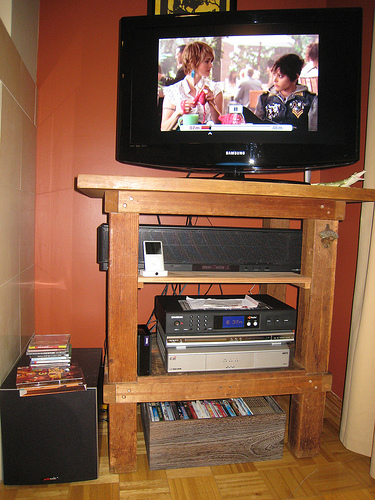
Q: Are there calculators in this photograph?
A: No, there are no calculators.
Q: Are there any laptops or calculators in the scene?
A: No, there are no calculators or laptops.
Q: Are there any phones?
A: Yes, there is a phone.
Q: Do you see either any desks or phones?
A: Yes, there is a phone.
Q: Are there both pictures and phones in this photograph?
A: Yes, there are both a phone and a picture.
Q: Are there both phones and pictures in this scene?
A: Yes, there are both a phone and a picture.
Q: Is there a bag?
A: No, there are no bags.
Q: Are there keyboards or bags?
A: No, there are no bags or keyboards.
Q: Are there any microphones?
A: No, there are no microphones.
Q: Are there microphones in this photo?
A: No, there are no microphones.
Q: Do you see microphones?
A: No, there are no microphones.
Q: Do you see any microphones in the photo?
A: No, there are no microphones.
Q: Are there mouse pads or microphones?
A: No, there are no microphones or mouse pads.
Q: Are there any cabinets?
A: No, there are no cabinets.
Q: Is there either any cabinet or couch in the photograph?
A: No, there are no cabinets or couches.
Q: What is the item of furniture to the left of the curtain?
A: The piece of furniture is a shelf.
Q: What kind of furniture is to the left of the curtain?
A: The piece of furniture is a shelf.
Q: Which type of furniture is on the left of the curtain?
A: The piece of furniture is a shelf.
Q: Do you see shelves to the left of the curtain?
A: Yes, there is a shelf to the left of the curtain.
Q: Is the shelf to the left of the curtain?
A: Yes, the shelf is to the left of the curtain.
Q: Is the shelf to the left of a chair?
A: No, the shelf is to the left of the curtain.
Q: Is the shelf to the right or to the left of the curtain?
A: The shelf is to the left of the curtain.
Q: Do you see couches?
A: No, there are no couches.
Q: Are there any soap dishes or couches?
A: No, there are no couches or soap dishes.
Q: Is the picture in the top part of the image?
A: Yes, the picture is in the top of the image.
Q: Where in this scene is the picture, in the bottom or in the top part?
A: The picture is in the top of the image.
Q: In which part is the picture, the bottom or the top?
A: The picture is in the top of the image.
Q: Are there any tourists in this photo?
A: No, there are no tourists.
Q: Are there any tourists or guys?
A: No, there are no tourists or guys.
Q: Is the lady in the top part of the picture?
A: Yes, the lady is in the top of the image.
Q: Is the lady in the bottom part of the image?
A: No, the lady is in the top of the image.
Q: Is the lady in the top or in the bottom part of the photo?
A: The lady is in the top of the image.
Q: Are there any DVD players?
A: Yes, there is a DVD player.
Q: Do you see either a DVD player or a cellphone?
A: Yes, there is a DVD player.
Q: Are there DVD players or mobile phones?
A: Yes, there is a DVD player.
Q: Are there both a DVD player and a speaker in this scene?
A: Yes, there are both a DVD player and a speaker.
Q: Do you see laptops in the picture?
A: No, there are no laptops.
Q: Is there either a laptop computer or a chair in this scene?
A: No, there are no laptops or chairs.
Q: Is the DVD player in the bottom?
A: Yes, the DVD player is in the bottom of the image.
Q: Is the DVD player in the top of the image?
A: No, the DVD player is in the bottom of the image.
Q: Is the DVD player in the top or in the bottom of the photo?
A: The DVD player is in the bottom of the image.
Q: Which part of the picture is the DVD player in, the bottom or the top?
A: The DVD player is in the bottom of the image.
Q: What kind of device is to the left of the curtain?
A: The device is a DVD player.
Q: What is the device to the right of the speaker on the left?
A: The device is a DVD player.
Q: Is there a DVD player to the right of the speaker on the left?
A: Yes, there is a DVD player to the right of the speaker.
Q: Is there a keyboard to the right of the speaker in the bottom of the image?
A: No, there is a DVD player to the right of the speaker.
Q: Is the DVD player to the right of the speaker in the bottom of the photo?
A: Yes, the DVD player is to the right of the speaker.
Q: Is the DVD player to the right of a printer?
A: No, the DVD player is to the right of the speaker.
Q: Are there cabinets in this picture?
A: No, there are no cabinets.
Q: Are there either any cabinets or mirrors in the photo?
A: No, there are no cabinets or mirrors.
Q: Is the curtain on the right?
A: Yes, the curtain is on the right of the image.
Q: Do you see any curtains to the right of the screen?
A: Yes, there is a curtain to the right of the screen.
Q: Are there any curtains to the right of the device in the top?
A: Yes, there is a curtain to the right of the screen.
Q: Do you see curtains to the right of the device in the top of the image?
A: Yes, there is a curtain to the right of the screen.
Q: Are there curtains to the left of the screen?
A: No, the curtain is to the right of the screen.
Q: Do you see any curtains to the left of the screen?
A: No, the curtain is to the right of the screen.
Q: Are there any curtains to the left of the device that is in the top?
A: No, the curtain is to the right of the screen.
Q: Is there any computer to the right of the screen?
A: No, there is a curtain to the right of the screen.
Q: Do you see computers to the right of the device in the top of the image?
A: No, there is a curtain to the right of the screen.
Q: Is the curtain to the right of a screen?
A: Yes, the curtain is to the right of a screen.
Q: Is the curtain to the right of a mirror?
A: No, the curtain is to the right of a screen.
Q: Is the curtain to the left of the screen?
A: No, the curtain is to the right of the screen.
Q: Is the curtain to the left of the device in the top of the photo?
A: No, the curtain is to the right of the screen.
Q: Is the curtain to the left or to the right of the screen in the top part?
A: The curtain is to the right of the screen.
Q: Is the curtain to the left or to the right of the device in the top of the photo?
A: The curtain is to the right of the screen.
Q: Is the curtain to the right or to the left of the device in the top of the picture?
A: The curtain is to the right of the screen.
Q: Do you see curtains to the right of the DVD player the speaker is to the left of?
A: Yes, there is a curtain to the right of the DVD player.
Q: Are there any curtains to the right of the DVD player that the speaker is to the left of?
A: Yes, there is a curtain to the right of the DVD player.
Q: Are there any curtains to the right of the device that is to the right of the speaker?
A: Yes, there is a curtain to the right of the DVD player.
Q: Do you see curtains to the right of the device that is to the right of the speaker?
A: Yes, there is a curtain to the right of the DVD player.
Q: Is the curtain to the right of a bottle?
A: No, the curtain is to the right of a DVD player.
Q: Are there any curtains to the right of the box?
A: Yes, there is a curtain to the right of the box.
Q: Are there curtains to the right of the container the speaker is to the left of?
A: Yes, there is a curtain to the right of the box.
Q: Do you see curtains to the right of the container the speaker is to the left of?
A: Yes, there is a curtain to the right of the box.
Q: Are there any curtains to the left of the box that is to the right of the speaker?
A: No, the curtain is to the right of the box.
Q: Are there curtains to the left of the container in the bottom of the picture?
A: No, the curtain is to the right of the box.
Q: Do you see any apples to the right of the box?
A: No, there is a curtain to the right of the box.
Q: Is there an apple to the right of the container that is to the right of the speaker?
A: No, there is a curtain to the right of the box.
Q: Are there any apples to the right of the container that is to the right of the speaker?
A: No, there is a curtain to the right of the box.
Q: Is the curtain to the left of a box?
A: No, the curtain is to the right of a box.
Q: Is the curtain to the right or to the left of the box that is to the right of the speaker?
A: The curtain is to the right of the box.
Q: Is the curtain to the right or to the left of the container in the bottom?
A: The curtain is to the right of the box.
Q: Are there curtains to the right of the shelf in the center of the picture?
A: Yes, there is a curtain to the right of the shelf.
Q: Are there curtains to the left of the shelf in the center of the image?
A: No, the curtain is to the right of the shelf.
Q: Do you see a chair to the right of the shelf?
A: No, there is a curtain to the right of the shelf.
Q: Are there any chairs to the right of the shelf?
A: No, there is a curtain to the right of the shelf.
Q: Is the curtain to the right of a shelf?
A: Yes, the curtain is to the right of a shelf.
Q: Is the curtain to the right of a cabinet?
A: No, the curtain is to the right of a shelf.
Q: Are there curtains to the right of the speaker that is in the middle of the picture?
A: Yes, there is a curtain to the right of the speaker.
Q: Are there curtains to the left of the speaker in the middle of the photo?
A: No, the curtain is to the right of the speaker.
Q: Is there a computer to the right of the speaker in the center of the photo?
A: No, there is a curtain to the right of the speaker.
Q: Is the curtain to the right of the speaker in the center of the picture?
A: Yes, the curtain is to the right of the speaker.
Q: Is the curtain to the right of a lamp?
A: No, the curtain is to the right of the speaker.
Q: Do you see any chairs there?
A: No, there are no chairs.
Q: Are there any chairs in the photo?
A: No, there are no chairs.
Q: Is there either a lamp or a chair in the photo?
A: No, there are no chairs or lamps.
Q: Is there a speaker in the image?
A: Yes, there is a speaker.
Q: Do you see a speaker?
A: Yes, there is a speaker.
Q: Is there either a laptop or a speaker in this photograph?
A: Yes, there is a speaker.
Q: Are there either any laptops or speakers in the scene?
A: Yes, there is a speaker.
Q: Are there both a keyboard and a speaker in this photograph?
A: No, there is a speaker but no keyboards.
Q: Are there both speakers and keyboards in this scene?
A: No, there is a speaker but no keyboards.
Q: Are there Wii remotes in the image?
A: No, there are no Wii remotes.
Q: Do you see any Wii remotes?
A: No, there are no Wii remotes.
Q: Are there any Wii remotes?
A: No, there are no Wii remotes.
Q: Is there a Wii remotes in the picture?
A: No, there are no Wii controllers.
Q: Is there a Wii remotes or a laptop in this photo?
A: No, there are no Wii controllers or laptops.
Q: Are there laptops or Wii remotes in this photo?
A: No, there are no Wii remotes or laptops.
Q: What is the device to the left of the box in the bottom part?
A: The device is a speaker.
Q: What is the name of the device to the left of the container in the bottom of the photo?
A: The device is a speaker.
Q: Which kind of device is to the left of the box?
A: The device is a speaker.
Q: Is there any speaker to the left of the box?
A: Yes, there is a speaker to the left of the box.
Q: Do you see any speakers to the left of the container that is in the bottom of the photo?
A: Yes, there is a speaker to the left of the box.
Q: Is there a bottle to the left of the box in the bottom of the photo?
A: No, there is a speaker to the left of the box.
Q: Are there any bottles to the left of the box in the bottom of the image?
A: No, there is a speaker to the left of the box.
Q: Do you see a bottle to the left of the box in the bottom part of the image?
A: No, there is a speaker to the left of the box.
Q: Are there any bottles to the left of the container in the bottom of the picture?
A: No, there is a speaker to the left of the box.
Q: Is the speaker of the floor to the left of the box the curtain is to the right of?
A: Yes, the speaker is to the left of the box.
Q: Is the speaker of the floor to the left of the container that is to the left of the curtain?
A: Yes, the speaker is to the left of the box.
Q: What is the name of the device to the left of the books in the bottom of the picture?
A: The device is a speaker.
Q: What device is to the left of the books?
A: The device is a speaker.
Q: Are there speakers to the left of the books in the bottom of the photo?
A: Yes, there is a speaker to the left of the books.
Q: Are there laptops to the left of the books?
A: No, there is a speaker to the left of the books.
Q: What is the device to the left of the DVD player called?
A: The device is a speaker.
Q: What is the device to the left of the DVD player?
A: The device is a speaker.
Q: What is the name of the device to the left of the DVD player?
A: The device is a speaker.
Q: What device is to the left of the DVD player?
A: The device is a speaker.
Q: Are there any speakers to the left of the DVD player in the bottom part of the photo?
A: Yes, there is a speaker to the left of the DVD player.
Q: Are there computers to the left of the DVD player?
A: No, there is a speaker to the left of the DVD player.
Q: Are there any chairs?
A: No, there are no chairs.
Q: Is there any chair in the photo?
A: No, there are no chairs.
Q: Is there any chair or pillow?
A: No, there are no chairs or pillows.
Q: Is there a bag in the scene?
A: No, there are no bags.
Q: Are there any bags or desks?
A: No, there are no bags or desks.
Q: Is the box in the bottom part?
A: Yes, the box is in the bottom of the image.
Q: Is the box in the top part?
A: No, the box is in the bottom of the image.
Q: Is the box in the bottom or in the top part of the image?
A: The box is in the bottom of the image.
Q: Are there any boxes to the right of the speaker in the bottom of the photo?
A: Yes, there is a box to the right of the speaker.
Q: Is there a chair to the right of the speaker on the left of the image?
A: No, there is a box to the right of the speaker.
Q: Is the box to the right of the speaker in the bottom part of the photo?
A: Yes, the box is to the right of the speaker.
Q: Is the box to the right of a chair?
A: No, the box is to the right of the speaker.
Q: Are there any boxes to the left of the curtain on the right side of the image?
A: Yes, there is a box to the left of the curtain.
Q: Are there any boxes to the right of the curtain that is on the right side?
A: No, the box is to the left of the curtain.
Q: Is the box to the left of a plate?
A: No, the box is to the left of the curtain.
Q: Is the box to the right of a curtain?
A: No, the box is to the left of a curtain.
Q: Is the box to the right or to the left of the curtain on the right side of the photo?
A: The box is to the left of the curtain.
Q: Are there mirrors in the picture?
A: No, there are no mirrors.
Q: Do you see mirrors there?
A: No, there are no mirrors.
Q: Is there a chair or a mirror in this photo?
A: No, there are no mirrors or chairs.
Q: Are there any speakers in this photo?
A: Yes, there is a speaker.